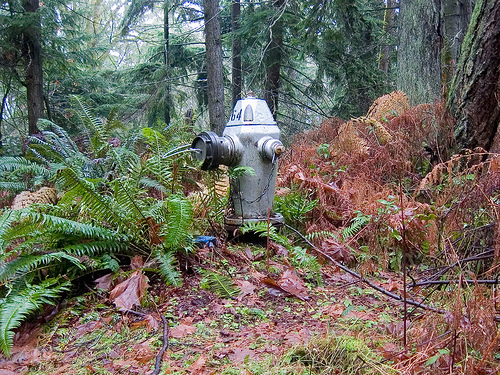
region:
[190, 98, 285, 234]
Silver fire hydrant.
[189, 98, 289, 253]
Silver fire hydrant with identifying numbers on it.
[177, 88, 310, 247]
Silver fire hydrants surrounded by shrubbery.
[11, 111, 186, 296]
Green shrubbery on forest floor.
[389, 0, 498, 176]
Tall pine tree trunks.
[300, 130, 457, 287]
Pink colored vegetation on the forest floor.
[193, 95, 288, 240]
Gray fire hydrant amongst shrubs.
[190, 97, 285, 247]
Gray fire hydrant surrounded by foliage.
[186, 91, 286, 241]
Silver and gray fire hydrant.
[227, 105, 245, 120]
Identifying numbers on a fire hydrant.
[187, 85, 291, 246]
a fire hydrant in the woods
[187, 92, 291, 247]
a silver fire hydrant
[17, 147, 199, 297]
a fern plant in the woods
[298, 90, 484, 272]
brown leaves in the forest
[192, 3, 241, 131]
the trunk of a pine tree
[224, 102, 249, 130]
the number 64 on a fire hydrant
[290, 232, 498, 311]
sticks in the forest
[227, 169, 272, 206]
a chain on a fire hydrant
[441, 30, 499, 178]
bark on a tree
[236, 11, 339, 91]
pine needles on the trees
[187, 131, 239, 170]
The large cylinder on the hydrant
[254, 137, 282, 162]
The smaller side cylinder on the hydrant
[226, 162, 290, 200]
The chain hanging from the hydrant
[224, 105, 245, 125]
The numbers on the hydrant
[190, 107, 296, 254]
A silver fire hydrant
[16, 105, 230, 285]
A green shrub next to the fire hydrant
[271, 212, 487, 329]
A long stick near the fire hydrant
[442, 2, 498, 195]
A tree trunk that has moss on it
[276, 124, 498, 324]
Dead bushes to the right of the hydrant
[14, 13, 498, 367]
A scene in the middle of the woods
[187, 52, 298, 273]
this is a fire hydrant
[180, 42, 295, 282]
a fire hydrant in the woods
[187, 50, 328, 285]
this is made from metal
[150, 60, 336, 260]
this is silver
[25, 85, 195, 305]
green fern plants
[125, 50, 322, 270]
a hydrant in the forest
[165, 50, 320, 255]
this is a silver fire hydrant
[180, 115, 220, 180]
this is where the hose goes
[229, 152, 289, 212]
this is a metal chain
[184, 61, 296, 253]
the hydrant is silver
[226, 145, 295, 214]
a chain on the hydrant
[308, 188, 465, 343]
the sticks are brown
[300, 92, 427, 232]
the leaves are reddish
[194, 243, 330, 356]
the leaves are on the ground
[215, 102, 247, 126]
the numbers are black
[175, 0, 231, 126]
the tree is tall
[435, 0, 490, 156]
green is growing up the tree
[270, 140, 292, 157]
the bolt is brass